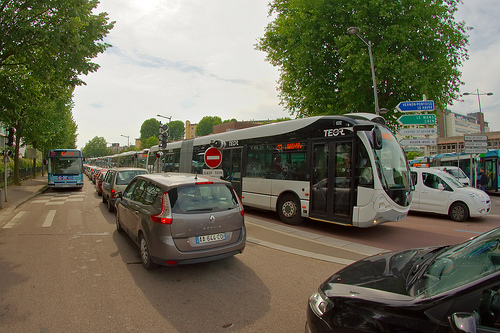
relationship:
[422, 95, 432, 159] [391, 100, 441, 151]
post has signs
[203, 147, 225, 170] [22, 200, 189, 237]
sign for crossing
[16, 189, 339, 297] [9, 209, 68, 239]
road has lines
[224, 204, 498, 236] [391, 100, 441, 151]
street has signs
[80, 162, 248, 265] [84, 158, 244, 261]
cars in line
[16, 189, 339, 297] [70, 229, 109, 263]
road has stains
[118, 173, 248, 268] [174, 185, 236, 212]
car has window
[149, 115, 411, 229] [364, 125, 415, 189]
bus has windshield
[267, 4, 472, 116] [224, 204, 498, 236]
tree near street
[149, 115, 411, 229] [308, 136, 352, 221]
bus has door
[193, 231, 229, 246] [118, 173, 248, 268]
plate on car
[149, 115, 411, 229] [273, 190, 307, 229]
bus has wheel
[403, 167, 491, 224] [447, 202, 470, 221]
car has wheel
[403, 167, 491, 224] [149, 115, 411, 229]
car near bus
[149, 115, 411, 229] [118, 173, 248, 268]
bus near car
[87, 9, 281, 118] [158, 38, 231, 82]
sky has clouds